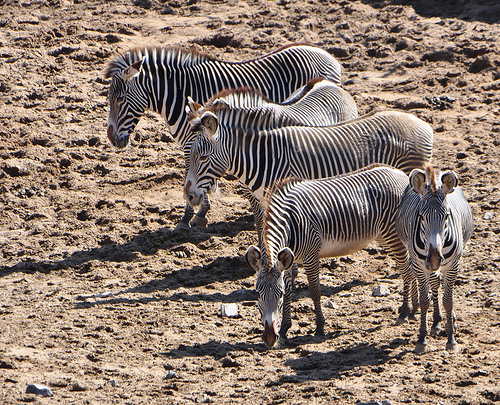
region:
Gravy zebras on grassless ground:
[99, 39, 479, 371]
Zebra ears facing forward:
[407, 165, 461, 197]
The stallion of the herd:
[101, 40, 344, 220]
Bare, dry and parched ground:
[8, 15, 103, 190]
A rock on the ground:
[215, 298, 247, 320]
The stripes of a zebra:
[152, 55, 174, 100]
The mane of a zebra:
[214, 84, 269, 99]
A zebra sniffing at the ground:
[243, 243, 299, 354]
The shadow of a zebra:
[0, 235, 173, 275]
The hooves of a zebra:
[412, 338, 460, 357]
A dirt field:
[1, 0, 498, 402]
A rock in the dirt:
[366, 280, 394, 302]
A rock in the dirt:
[218, 300, 245, 317]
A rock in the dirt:
[26, 383, 51, 397]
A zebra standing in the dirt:
[100, 35, 341, 231]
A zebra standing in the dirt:
[181, 80, 358, 125]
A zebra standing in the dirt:
[185, 96, 430, 203]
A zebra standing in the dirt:
[245, 160, 415, 345]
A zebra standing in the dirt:
[396, 166, 471, 348]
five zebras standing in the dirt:
[87, 42, 462, 353]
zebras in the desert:
[82, 23, 489, 386]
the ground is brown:
[2, 6, 498, 393]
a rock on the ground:
[209, 294, 251, 324]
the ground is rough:
[5, 2, 486, 390]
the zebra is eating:
[232, 159, 419, 351]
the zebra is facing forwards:
[397, 164, 475, 352]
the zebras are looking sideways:
[95, 36, 417, 238]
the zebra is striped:
[81, 37, 339, 151]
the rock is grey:
[24, 373, 56, 402]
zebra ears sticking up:
[401, 169, 463, 194]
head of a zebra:
[100, 50, 151, 155]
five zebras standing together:
[96, 29, 480, 371]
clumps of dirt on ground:
[22, 143, 107, 228]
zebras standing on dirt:
[100, 36, 495, 361]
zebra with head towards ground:
[235, 235, 296, 346]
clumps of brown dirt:
[415, 10, 496, 91]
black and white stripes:
[310, 188, 375, 244]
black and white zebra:
[390, 150, 482, 362]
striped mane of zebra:
[105, 43, 206, 69]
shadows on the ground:
[57, 235, 233, 325]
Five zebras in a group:
[76, 31, 473, 349]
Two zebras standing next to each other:
[158, 83, 428, 188]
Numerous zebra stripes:
[73, 33, 485, 341]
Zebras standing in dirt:
[50, 16, 472, 341]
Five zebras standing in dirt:
[72, 18, 492, 378]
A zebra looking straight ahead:
[392, 146, 469, 359]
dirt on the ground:
[15, 145, 160, 391]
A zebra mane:
[97, 39, 205, 74]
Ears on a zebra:
[238, 239, 300, 277]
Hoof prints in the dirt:
[35, 108, 207, 387]